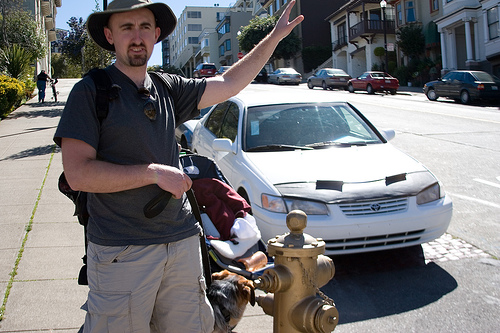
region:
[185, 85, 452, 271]
a car parked on street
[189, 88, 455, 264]
a white Toyota Camry vehicle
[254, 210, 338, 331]
a dull yellow fire hydrant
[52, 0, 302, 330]
a man waving on sidewalk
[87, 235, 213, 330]
a pair of light beige pants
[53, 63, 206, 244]
a dark grey t-shirt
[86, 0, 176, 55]
a large grey hat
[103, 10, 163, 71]
a man's face with goatee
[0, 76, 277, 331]
a block paved city sidewalk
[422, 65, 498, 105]
a parked black car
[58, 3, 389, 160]
Man is waving at someone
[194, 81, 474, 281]
The car is parked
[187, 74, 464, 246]
The car is white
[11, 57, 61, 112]
Man is pushing his bike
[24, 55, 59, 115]
Man is on the sidewalk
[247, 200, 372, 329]
The fire hydrant is yellow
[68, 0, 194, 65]
The man is wearing a hat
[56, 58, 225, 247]
The man's shirt is charcoal colored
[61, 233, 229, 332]
Man is wearing tan pants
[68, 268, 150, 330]
Pants have a pocket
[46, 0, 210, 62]
man wearing hat with brim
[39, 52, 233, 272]
man wearing grey shirt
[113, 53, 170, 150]
man has sunglasses tucked in shirt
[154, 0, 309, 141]
man has arm extended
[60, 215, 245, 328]
man wearing khaki bottoms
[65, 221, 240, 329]
bottoms have multiple pockets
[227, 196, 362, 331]
fire hydrant is gold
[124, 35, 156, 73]
man has brown goatee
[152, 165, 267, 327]
man hold dog leash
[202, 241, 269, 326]
dog standing next to man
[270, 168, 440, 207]
a black hood bra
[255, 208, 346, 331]
a gold firehydrant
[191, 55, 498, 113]
cars parked up a hill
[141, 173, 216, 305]
a black dog leash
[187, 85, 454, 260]
parked four door white car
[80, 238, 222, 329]
tan cargo shorts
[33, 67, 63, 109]
a person with a bike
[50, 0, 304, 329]
a man with his arm out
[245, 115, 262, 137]
sticker in the window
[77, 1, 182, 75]
man wearing a hat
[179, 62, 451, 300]
a white car is parked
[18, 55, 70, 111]
a person with a bike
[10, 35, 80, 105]
a person with a bike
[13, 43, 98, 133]
a person with a bike